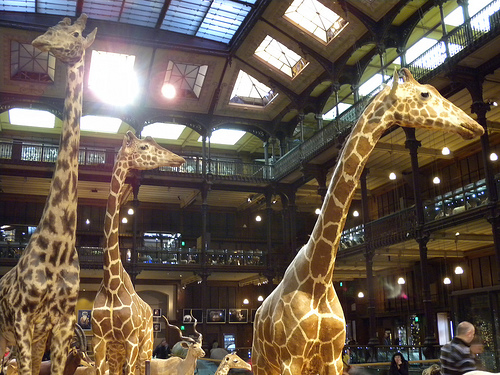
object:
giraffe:
[248, 66, 486, 375]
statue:
[0, 13, 98, 374]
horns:
[73, 12, 93, 28]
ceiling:
[0, 1, 376, 138]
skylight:
[82, 48, 145, 108]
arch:
[202, 121, 271, 178]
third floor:
[0, 0, 500, 184]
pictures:
[204, 310, 227, 326]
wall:
[130, 283, 304, 349]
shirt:
[437, 338, 473, 375]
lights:
[450, 266, 466, 276]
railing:
[424, 181, 500, 223]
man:
[440, 321, 476, 375]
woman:
[386, 350, 407, 375]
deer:
[146, 309, 206, 375]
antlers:
[160, 313, 195, 343]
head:
[376, 65, 487, 139]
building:
[0, 0, 500, 375]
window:
[225, 64, 280, 107]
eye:
[414, 87, 433, 101]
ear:
[392, 67, 410, 83]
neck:
[307, 106, 394, 297]